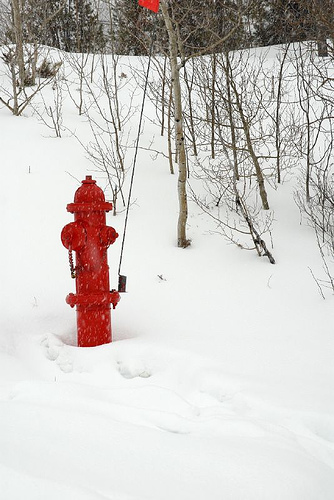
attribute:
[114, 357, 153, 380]
footprints — deep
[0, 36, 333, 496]
snow — white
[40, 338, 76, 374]
footprints — deep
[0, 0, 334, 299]
trees — green, pine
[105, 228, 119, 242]
cap — small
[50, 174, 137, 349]
hydrant — tall, red, fire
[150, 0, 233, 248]
tree — young, bare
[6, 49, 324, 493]
field — white, snowy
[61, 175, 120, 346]
hydrant — red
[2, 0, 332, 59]
pine trees — large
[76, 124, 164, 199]
snow — white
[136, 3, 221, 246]
birch tree — white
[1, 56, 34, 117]
birch tree — white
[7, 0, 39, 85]
birch tree — white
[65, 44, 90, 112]
birch tree — white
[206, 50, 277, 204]
birch tree — white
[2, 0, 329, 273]
trees — bare, gray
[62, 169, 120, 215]
cap — large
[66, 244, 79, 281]
chain — rusty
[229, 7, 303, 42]
sky — dark